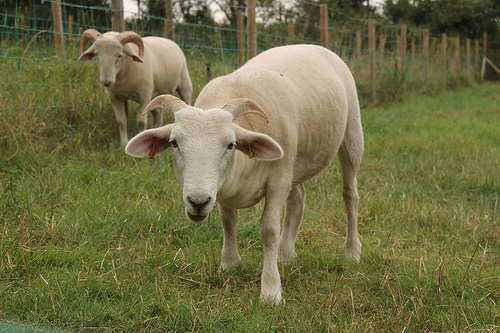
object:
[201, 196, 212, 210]
nostrils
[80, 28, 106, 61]
horns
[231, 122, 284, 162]
ear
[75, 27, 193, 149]
sheep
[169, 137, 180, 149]
eye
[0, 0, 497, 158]
fence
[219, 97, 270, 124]
horn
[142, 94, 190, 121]
horn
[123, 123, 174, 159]
ear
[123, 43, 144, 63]
ear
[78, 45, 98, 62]
ear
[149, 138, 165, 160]
tag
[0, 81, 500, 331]
field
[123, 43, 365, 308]
sheep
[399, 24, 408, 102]
fence post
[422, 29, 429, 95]
fence post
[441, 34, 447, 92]
fence post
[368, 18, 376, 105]
fence post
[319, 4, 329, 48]
fence post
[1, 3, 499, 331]
grass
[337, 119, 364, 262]
leg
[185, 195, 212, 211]
nose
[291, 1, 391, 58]
trees